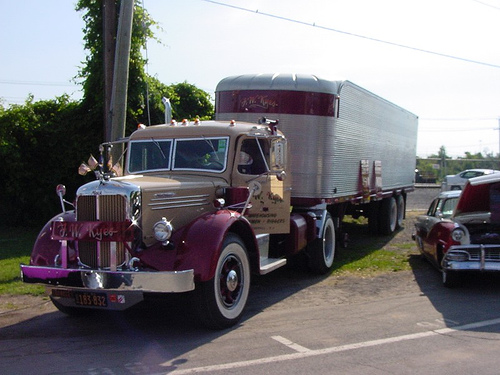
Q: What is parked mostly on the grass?
A: The purple and tan truck cab.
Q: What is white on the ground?
A: Lines.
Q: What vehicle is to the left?
A: Truck.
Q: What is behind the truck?
A: Trailer.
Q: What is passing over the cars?
A: Wires.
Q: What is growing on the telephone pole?
A: Vines.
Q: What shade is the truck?
A: Purple, gold and white.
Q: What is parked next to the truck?
A: Car.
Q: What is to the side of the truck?
A: Trees.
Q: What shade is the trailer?
A: Grey.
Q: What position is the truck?
A: Parked.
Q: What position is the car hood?
A: Up.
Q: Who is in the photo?
A: No people.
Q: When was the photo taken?
A: During the daytime.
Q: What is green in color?
A: The grass.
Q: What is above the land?
A: The sky.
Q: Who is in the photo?
A: Nobody.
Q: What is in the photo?
A: Vehicles.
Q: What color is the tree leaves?
A: Green.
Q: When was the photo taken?
A: Daytime.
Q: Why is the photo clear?
A: Its during the day.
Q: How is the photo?
A: Clear.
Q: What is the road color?
A: Grey.